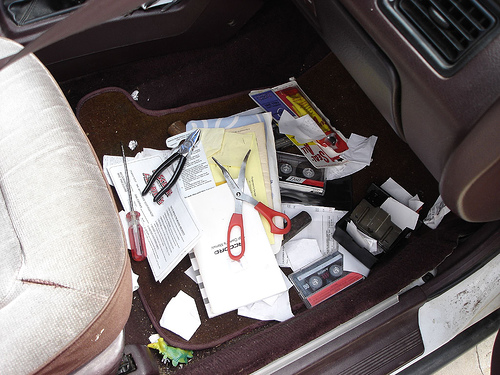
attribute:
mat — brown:
[94, 76, 367, 330]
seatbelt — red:
[2, 2, 147, 77]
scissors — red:
[176, 126, 312, 291]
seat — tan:
[1, 24, 137, 373]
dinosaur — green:
[143, 337, 201, 368]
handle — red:
[256, 202, 288, 233]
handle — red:
[223, 215, 245, 259]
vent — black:
[378, 1, 498, 78]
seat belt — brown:
[2, 0, 155, 77]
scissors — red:
[210, 148, 290, 260]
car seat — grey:
[0, 36, 133, 373]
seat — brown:
[15, 90, 162, 371]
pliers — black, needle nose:
[138, 123, 201, 202]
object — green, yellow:
[142, 333, 193, 367]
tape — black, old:
[287, 248, 368, 309]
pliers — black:
[134, 124, 197, 192]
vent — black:
[143, 90, 367, 221]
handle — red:
[224, 202, 297, 259]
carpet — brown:
[75, 79, 447, 352]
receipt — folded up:
[162, 290, 209, 345]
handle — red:
[226, 202, 290, 261]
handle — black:
[140, 149, 188, 201]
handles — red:
[215, 195, 294, 261]